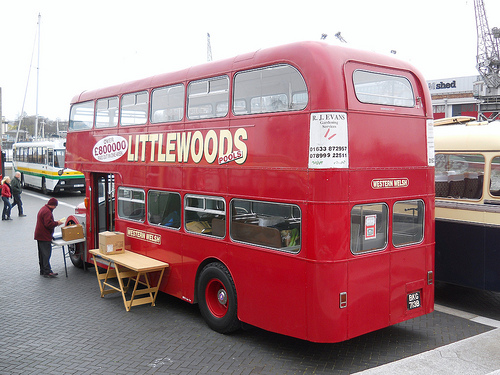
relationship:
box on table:
[98, 230, 126, 257] [86, 249, 168, 314]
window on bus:
[231, 58, 309, 116] [65, 41, 439, 344]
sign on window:
[363, 213, 378, 241] [349, 201, 390, 256]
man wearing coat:
[34, 196, 65, 277] [35, 205, 58, 243]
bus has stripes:
[10, 140, 85, 197] [12, 166, 84, 181]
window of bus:
[185, 74, 234, 122] [65, 41, 439, 344]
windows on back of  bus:
[349, 198, 428, 257] [320, 42, 438, 346]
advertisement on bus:
[363, 213, 378, 241] [65, 41, 439, 344]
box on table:
[60, 223, 85, 242] [49, 231, 90, 280]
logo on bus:
[370, 177, 410, 190] [65, 41, 439, 344]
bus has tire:
[10, 140, 85, 197] [40, 179, 52, 196]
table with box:
[49, 231, 90, 280] [60, 223, 85, 242]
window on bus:
[351, 66, 417, 110] [65, 41, 439, 344]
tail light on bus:
[424, 269, 435, 288] [65, 41, 439, 344]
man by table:
[34, 196, 65, 277] [49, 231, 90, 280]